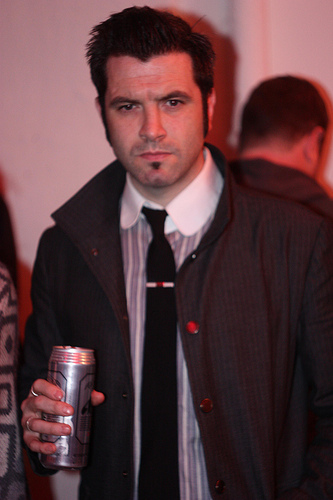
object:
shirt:
[119, 150, 220, 500]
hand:
[16, 374, 107, 455]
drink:
[37, 344, 94, 469]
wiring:
[47, 368, 68, 446]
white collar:
[121, 145, 225, 236]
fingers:
[27, 437, 59, 456]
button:
[212, 478, 222, 491]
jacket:
[14, 142, 332, 499]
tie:
[139, 206, 180, 499]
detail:
[156, 280, 164, 288]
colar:
[165, 147, 224, 237]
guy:
[20, 5, 331, 498]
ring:
[29, 381, 39, 398]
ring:
[25, 417, 32, 431]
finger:
[26, 417, 72, 440]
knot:
[142, 206, 168, 237]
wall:
[0, 1, 97, 151]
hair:
[150, 160, 161, 171]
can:
[37, 342, 95, 472]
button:
[186, 317, 199, 336]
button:
[199, 394, 215, 417]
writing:
[74, 368, 92, 445]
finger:
[29, 378, 64, 400]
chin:
[131, 161, 181, 191]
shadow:
[212, 38, 243, 155]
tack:
[143, 280, 173, 289]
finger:
[30, 396, 74, 418]